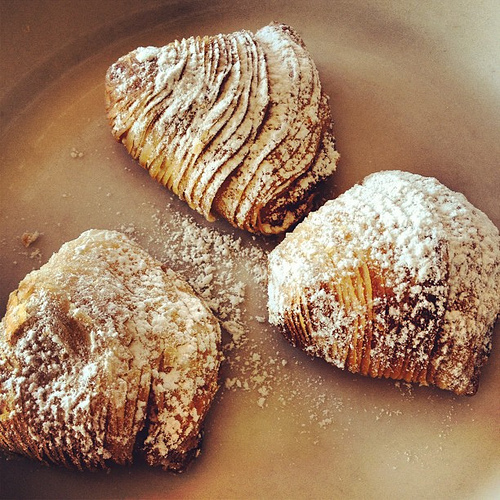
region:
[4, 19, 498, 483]
three desserts on a plate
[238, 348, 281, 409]
powdered sugar on plate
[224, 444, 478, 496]
white plate where desserts are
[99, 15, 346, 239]
italian pastry with sugar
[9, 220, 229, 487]
italian pastry shaped like a shell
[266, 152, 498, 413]
italian dessert with powdered sugar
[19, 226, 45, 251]
crumb on a plate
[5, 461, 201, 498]
shadow casted on a plate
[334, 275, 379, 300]
layers of a dessert crust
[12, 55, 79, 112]
dip in the plate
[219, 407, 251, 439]
the plate is red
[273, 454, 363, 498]
the plate is red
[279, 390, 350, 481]
the plate is red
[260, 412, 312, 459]
the plate is red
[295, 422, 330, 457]
the plate is red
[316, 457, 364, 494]
the plate is red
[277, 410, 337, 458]
the plate is red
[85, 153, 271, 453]
the powder is scattered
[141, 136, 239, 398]
the powder is scattered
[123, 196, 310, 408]
the powder is scattered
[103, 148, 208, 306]
the powder is scattered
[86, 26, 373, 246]
pastries with powdered sugar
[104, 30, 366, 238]
they appear to be delicate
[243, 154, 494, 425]
they appear to be made in flaky layers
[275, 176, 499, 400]
the pastries are brown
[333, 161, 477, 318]
the sugar is white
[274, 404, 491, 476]
the table is beige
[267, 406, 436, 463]
the surface of the table appears smooth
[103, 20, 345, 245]
the pastries are cone shaped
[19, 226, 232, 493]
a yummy snack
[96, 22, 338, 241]
a confectioner's delight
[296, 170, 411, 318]
the bread is red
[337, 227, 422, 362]
the bread is red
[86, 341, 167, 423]
the bread is red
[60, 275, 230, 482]
the bread is red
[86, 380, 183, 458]
the bread is red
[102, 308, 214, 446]
the bread is red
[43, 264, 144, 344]
the bread is red